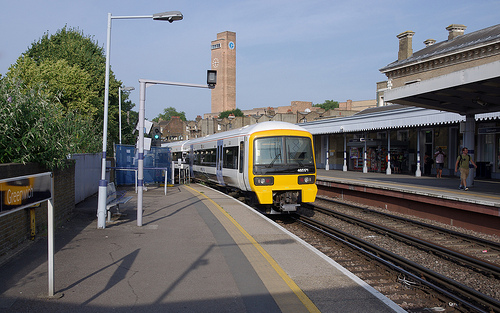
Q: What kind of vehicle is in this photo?
A: Train.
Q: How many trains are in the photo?
A: One.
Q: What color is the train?
A: Yellow, white and black.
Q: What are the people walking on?
A: Platform.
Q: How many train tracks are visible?
A: Two.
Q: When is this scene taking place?
A: Day time.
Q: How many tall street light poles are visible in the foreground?
A: Two.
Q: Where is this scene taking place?
A: At a train station.